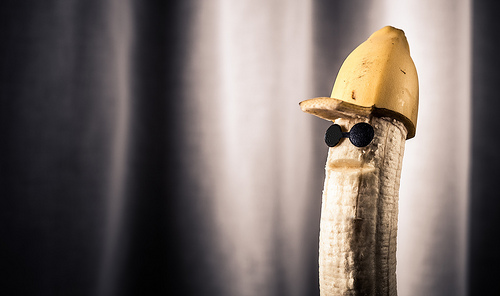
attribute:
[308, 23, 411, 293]
banana — yellow, brown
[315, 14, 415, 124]
hat — yellow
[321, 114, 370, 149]
glasses — black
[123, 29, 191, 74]
curtain — grey, white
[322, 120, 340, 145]
eye — black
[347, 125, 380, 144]
eye — black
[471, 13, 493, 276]
wall — black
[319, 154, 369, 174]
mouth — small